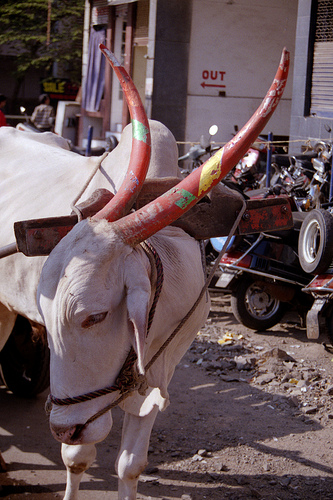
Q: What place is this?
A: It is a street.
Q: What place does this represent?
A: It represents the street.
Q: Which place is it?
A: It is a street.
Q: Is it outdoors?
A: Yes, it is outdoors.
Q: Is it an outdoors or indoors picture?
A: It is outdoors.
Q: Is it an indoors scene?
A: No, it is outdoors.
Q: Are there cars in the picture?
A: No, there are no cars.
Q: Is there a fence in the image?
A: No, there are no fences.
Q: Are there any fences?
A: No, there are no fences.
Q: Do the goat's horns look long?
A: Yes, the horns are long.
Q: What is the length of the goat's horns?
A: The horns are long.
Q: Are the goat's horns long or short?
A: The horns are long.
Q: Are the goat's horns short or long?
A: The horns are long.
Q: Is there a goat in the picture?
A: Yes, there is a goat.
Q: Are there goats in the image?
A: Yes, there is a goat.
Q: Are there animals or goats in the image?
A: Yes, there is a goat.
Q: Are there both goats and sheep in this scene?
A: No, there is a goat but no sheep.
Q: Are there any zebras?
A: No, there are no zebras.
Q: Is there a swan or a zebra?
A: No, there are no zebras or swans.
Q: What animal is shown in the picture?
A: The animal is a goat.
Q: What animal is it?
A: The animal is a goat.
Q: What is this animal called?
A: This is a goat.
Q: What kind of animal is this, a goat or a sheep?
A: This is a goat.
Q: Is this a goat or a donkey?
A: This is a goat.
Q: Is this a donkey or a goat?
A: This is a goat.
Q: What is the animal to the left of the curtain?
A: The animal is a goat.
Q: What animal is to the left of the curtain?
A: The animal is a goat.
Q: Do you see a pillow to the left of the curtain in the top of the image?
A: No, there is a goat to the left of the curtain.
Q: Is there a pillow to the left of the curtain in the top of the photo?
A: No, there is a goat to the left of the curtain.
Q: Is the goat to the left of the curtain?
A: Yes, the goat is to the left of the curtain.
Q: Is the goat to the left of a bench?
A: No, the goat is to the left of the curtain.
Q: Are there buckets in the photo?
A: No, there are no buckets.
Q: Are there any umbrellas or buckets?
A: No, there are no buckets or umbrellas.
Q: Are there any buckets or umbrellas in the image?
A: No, there are no buckets or umbrellas.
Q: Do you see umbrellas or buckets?
A: No, there are no buckets or umbrellas.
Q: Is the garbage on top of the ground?
A: Yes, the garbage is on top of the ground.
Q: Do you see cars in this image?
A: No, there are no cars.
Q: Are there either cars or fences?
A: No, there are no cars or fences.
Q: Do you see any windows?
A: Yes, there is a window.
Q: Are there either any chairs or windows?
A: Yes, there is a window.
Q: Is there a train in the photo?
A: No, there are no trains.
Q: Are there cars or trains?
A: No, there are no trains or cars.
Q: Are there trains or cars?
A: No, there are no trains or cars.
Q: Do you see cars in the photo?
A: No, there are no cars.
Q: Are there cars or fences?
A: No, there are no cars or fences.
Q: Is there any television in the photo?
A: No, there are no televisions.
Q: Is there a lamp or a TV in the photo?
A: No, there are no televisions or lamps.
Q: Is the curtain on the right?
A: Yes, the curtain is on the right of the image.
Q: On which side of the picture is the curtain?
A: The curtain is on the right of the image.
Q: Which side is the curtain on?
A: The curtain is on the right of the image.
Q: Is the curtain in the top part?
A: Yes, the curtain is in the top of the image.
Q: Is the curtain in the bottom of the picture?
A: No, the curtain is in the top of the image.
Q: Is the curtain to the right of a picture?
A: No, the curtain is to the right of a goat.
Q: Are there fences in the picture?
A: No, there are no fences.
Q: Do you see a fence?
A: No, there are no fences.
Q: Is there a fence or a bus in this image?
A: No, there are no fences or buses.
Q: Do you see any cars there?
A: No, there are no cars.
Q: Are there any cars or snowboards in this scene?
A: No, there are no cars or snowboards.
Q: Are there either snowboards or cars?
A: No, there are no cars or snowboards.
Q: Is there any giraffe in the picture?
A: No, there are no giraffes.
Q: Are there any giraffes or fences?
A: No, there are no giraffes or fences.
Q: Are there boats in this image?
A: No, there are no boats.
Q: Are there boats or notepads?
A: No, there are no boats or notepads.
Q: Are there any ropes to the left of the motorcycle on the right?
A: Yes, there is a rope to the left of the motorbike.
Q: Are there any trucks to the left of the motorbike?
A: No, there is a rope to the left of the motorbike.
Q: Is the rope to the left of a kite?
A: No, the rope is to the left of the motorbike.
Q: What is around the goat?
A: The rope is around the goat.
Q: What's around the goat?
A: The rope is around the goat.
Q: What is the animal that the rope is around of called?
A: The animal is a goat.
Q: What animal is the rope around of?
A: The rope is around the goat.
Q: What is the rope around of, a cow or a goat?
A: The rope is around a goat.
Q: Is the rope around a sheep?
A: No, the rope is around the goat.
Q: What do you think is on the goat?
A: The rope is on the goat.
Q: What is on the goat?
A: The rope is on the goat.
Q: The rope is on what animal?
A: The rope is on the goat.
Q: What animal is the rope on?
A: The rope is on the goat.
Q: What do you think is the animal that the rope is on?
A: The animal is a goat.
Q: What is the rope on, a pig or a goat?
A: The rope is on a goat.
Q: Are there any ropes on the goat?
A: Yes, there is a rope on the goat.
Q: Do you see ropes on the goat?
A: Yes, there is a rope on the goat.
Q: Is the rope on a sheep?
A: No, the rope is on the goat.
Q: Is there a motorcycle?
A: Yes, there is a motorcycle.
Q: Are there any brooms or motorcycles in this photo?
A: Yes, there is a motorcycle.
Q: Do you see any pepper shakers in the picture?
A: No, there are no pepper shakers.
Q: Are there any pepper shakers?
A: No, there are no pepper shakers.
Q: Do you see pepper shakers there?
A: No, there are no pepper shakers.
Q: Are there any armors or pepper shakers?
A: No, there are no pepper shakers or armors.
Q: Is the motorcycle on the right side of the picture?
A: Yes, the motorcycle is on the right of the image.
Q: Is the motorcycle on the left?
A: No, the motorcycle is on the right of the image.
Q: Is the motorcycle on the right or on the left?
A: The motorcycle is on the right of the image.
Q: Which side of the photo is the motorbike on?
A: The motorbike is on the right of the image.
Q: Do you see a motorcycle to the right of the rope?
A: Yes, there is a motorcycle to the right of the rope.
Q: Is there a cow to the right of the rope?
A: No, there is a motorcycle to the right of the rope.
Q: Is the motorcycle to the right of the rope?
A: Yes, the motorcycle is to the right of the rope.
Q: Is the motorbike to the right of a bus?
A: No, the motorbike is to the right of the rope.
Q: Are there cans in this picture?
A: No, there are no cans.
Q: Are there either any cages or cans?
A: No, there are no cans or cages.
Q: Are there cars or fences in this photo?
A: No, there are no cars or fences.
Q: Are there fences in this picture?
A: No, there are no fences.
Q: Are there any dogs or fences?
A: No, there are no fences or dogs.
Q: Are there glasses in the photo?
A: No, there are no glasses.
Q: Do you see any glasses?
A: No, there are no glasses.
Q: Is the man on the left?
A: Yes, the man is on the left of the image.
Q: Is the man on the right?
A: No, the man is on the left of the image.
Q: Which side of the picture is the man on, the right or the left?
A: The man is on the left of the image.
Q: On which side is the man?
A: The man is on the left of the image.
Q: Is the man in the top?
A: Yes, the man is in the top of the image.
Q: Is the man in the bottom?
A: No, the man is in the top of the image.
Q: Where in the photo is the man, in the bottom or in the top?
A: The man is in the top of the image.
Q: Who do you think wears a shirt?
A: The man wears a shirt.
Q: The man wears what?
A: The man wears a shirt.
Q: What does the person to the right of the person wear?
A: The man wears a shirt.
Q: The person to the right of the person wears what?
A: The man wears a shirt.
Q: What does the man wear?
A: The man wears a shirt.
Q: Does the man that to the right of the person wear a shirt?
A: Yes, the man wears a shirt.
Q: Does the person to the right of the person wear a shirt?
A: Yes, the man wears a shirt.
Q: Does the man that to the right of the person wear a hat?
A: No, the man wears a shirt.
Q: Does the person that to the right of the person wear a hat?
A: No, the man wears a shirt.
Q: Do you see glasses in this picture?
A: No, there are no glasses.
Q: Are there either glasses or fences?
A: No, there are no glasses or fences.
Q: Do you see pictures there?
A: No, there are no pictures.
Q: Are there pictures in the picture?
A: No, there are no pictures.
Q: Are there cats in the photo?
A: No, there are no cats.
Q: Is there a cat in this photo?
A: No, there are no cats.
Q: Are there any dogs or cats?
A: No, there are no cats or dogs.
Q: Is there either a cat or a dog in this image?
A: No, there are no cats or dogs.